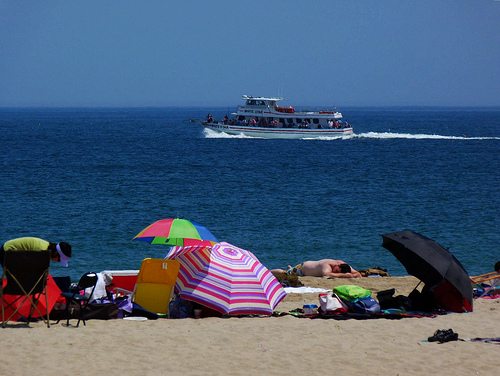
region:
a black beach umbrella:
[378, 226, 478, 309]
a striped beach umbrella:
[167, 241, 287, 313]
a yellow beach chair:
[129, 256, 182, 316]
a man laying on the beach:
[275, 256, 361, 279]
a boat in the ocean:
[190, 94, 358, 141]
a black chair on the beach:
[61, 271, 100, 326]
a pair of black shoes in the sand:
[424, 325, 461, 345]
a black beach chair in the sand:
[1, 246, 54, 326]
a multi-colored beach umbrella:
[132, 213, 222, 242]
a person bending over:
[0, 234, 76, 266]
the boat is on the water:
[211, 88, 358, 147]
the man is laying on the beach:
[291, 257, 363, 275]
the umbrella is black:
[412, 232, 445, 263]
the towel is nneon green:
[340, 283, 357, 299]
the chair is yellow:
[145, 273, 161, 297]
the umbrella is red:
[15, 300, 43, 315]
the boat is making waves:
[361, 128, 402, 142]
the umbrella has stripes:
[221, 268, 246, 297]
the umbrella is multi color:
[159, 220, 194, 235]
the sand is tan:
[282, 334, 316, 360]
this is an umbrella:
[210, 245, 257, 311]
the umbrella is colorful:
[213, 253, 268, 309]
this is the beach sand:
[263, 320, 302, 356]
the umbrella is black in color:
[402, 236, 445, 271]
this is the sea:
[280, 149, 387, 229]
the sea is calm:
[267, 140, 369, 227]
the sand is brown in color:
[274, 313, 326, 359]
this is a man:
[298, 247, 352, 279]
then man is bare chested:
[304, 251, 331, 274]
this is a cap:
[60, 252, 70, 265]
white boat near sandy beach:
[186, 92, 356, 142]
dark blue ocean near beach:
[1, 103, 498, 283]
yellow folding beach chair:
[101, 253, 181, 320]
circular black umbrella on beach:
[361, 225, 477, 317]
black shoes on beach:
[423, 324, 460, 344]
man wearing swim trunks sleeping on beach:
[258, 256, 365, 279]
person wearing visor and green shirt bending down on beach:
[1, 232, 76, 324]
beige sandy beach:
[0, 268, 498, 375]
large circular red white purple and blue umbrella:
[157, 233, 290, 317]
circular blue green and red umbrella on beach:
[129, 208, 224, 254]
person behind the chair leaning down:
[6, 231, 76, 290]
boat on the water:
[183, 85, 351, 147]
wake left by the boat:
[356, 128, 487, 145]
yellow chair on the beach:
[133, 257, 176, 320]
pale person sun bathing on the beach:
[274, 248, 351, 280]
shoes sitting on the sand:
[428, 323, 460, 348]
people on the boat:
[214, 110, 293, 130]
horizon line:
[19, 95, 166, 125]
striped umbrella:
[174, 252, 279, 326]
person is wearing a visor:
[54, 237, 68, 272]